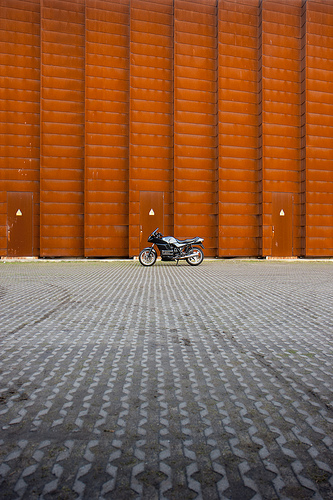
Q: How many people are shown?
A: Zero.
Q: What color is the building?
A: Red.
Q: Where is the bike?
A: By the building.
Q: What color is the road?
A: Black.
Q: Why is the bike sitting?
A: It is parked.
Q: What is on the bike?
A: Nothing.